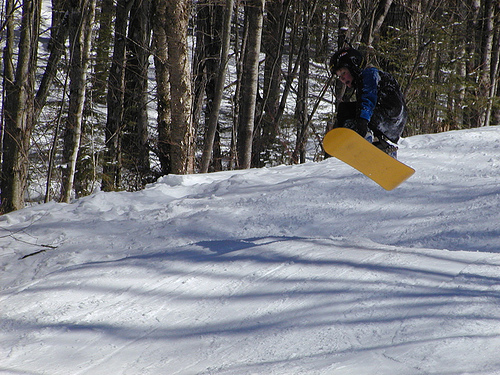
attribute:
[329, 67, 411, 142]
coat — blue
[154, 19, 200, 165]
winter tree — brown, bare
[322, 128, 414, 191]
snowboard — yellow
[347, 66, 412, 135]
coat — black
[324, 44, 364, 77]
helmet — snow, boarder's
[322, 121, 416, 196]
board — yellow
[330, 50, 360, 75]
helmet — black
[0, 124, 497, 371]
snow — white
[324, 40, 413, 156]
snowboarder — leaping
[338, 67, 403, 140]
jacket — black, blue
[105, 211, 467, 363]
snow — white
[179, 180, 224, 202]
snow clump — clumpy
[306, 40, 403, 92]
helmet — black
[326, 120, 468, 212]
snowboard — yellow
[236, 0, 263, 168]
tree — green, pine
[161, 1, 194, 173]
tree — green, pine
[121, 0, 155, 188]
tree — green, pine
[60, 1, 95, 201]
tree — green, pine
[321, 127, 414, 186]
snowboard — yellow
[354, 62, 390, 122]
jacket — blue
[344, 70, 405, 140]
coat — blue